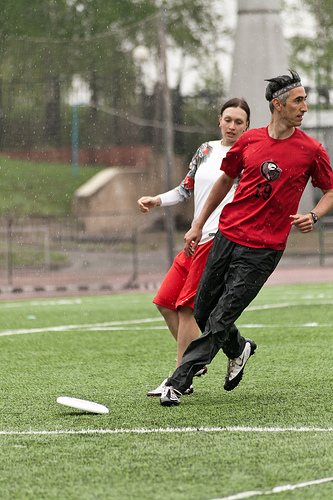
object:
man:
[161, 69, 333, 404]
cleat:
[146, 375, 198, 394]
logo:
[253, 157, 283, 202]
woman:
[138, 98, 251, 383]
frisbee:
[55, 396, 110, 415]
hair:
[265, 65, 300, 116]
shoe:
[160, 336, 258, 406]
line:
[0, 313, 327, 499]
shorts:
[152, 237, 216, 312]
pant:
[165, 227, 283, 394]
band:
[264, 77, 302, 99]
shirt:
[213, 124, 333, 250]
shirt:
[157, 137, 247, 247]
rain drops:
[0, 0, 333, 301]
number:
[253, 182, 272, 201]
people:
[136, 71, 333, 407]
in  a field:
[0, 270, 333, 498]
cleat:
[224, 341, 259, 392]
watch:
[310, 210, 320, 225]